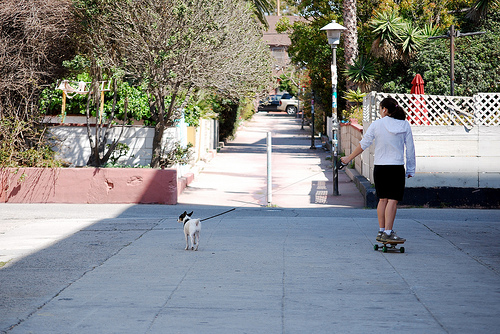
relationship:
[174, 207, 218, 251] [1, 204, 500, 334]
dog on ground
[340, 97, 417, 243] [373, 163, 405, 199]
person wearing shorts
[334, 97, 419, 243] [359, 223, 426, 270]
person on skateboard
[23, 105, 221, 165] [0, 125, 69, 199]
building in yard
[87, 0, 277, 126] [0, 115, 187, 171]
tree in yard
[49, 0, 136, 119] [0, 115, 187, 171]
tree in yard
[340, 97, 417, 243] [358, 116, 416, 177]
person wearing hoodie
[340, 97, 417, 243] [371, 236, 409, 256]
person riding skateboard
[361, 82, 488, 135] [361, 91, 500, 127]
lattice atop lattice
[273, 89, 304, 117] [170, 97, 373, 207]
car at end of alley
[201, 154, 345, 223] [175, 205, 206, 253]
leash on dog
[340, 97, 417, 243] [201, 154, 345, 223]
person pulling leash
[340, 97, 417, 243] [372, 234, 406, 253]
person on skateboard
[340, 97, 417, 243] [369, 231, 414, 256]
person on skateboard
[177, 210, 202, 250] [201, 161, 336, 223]
dog on leash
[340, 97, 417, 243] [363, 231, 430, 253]
person on skateboard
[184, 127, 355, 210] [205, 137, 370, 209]
sunlight on ground